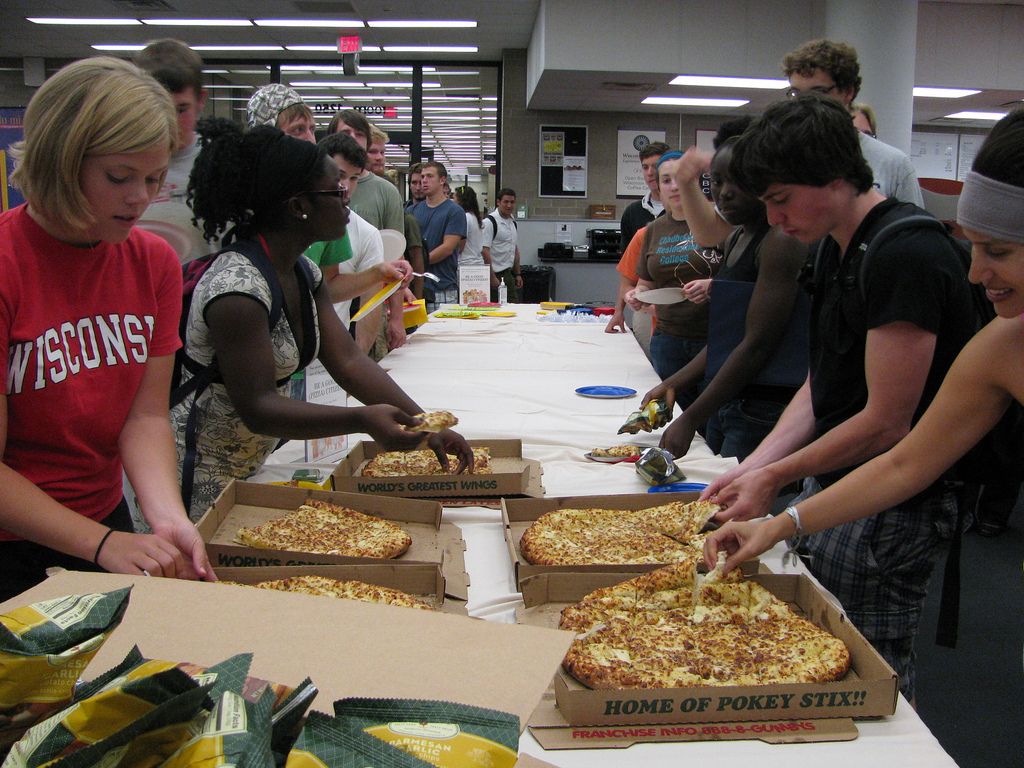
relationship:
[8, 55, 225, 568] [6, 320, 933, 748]
person standing table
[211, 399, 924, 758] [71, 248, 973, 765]
pizza on table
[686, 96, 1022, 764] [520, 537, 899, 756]
lady grabbing pizza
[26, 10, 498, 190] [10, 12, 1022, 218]
lights on ceiling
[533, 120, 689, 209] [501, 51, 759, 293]
pictures on wall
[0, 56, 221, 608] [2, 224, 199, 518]
person wears shirt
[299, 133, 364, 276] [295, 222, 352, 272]
boy wearing shirt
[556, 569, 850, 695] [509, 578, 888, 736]
pizza in box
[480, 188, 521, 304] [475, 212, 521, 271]
person wearing shirt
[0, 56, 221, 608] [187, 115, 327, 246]
person has dread locks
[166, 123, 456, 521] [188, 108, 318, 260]
woman with dread locks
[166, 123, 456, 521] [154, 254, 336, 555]
woman in dress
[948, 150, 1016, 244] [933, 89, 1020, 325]
grey headband on woman's head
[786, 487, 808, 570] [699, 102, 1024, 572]
silver bracelet on lady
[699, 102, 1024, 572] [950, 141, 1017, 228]
lady with grey headband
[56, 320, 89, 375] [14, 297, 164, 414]
white c in wisconsin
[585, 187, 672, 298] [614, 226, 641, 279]
right orange shirt sleeve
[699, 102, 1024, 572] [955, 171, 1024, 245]
lady wearing grey headband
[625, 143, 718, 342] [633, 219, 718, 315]
person wearing shirt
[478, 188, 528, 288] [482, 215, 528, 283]
person wearing shirt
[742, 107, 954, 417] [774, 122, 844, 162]
man has hair